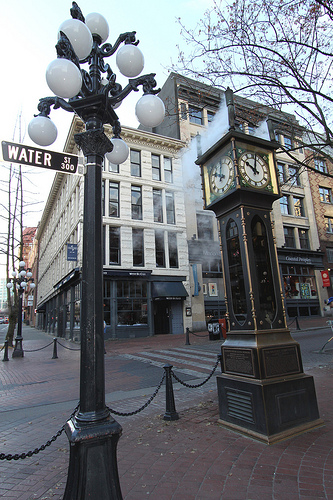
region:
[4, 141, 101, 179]
street sign on pole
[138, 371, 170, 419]
chain on black post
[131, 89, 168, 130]
round white bulb on street light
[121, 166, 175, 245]
windows on city building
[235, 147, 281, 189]
clock face on tower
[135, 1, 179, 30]
blue of daytime sky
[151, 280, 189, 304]
black awning over door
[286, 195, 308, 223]
light reflections on window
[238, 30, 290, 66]
bare limbs on tree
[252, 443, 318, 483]
red bricks on sidewalk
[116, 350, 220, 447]
black metal chain and pole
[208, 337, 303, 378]
gol writing on two black plaques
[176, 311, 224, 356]
black and white newspaper stand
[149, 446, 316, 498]
squares of brick pavers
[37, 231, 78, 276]
blue and white flag on building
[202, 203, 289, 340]
a case with two glass pieces in front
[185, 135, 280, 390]
clock tower with two clocks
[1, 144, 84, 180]
street sign that says water street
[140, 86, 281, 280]
smoke coming out of clock tower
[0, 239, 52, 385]
street light with many white globes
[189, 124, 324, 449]
Black tower clock sitting on sidewalk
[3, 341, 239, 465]
Black chain attached to poles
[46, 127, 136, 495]
Black street light post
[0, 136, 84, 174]
Black and white street name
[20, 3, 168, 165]
White globes attached to light post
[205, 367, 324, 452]
Base of tower clock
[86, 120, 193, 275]
Windows on front of white building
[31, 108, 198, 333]
White building with lots of windows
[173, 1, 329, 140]
Tree branches hanging over building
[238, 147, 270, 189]
Face of tower clock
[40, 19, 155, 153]
lights on the pole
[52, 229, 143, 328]
black pole below the light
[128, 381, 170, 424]
chain attached to the pole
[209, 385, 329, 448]
base of the structure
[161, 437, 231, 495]
lines on the ground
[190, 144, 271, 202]
two faces of clocks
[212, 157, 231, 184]
hands on the clock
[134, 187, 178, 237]
windows on the building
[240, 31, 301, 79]
branches on the tree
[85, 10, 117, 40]
top light on the pole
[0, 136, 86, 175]
Street sign attached to a pole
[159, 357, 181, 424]
Short post anchored to the ground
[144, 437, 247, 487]
Cobblestone sidewalk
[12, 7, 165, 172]
Rack of round outdoor lights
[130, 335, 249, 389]
Crosswalk in the middle of the street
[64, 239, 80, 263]
Street sign mounted to a building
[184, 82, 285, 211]
Outdoor clock with steam coming out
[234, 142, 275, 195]
Outdoor clock with Roman numeral face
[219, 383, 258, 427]
Vents on the base of an outdoor clock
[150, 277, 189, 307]
Awning over a doorway